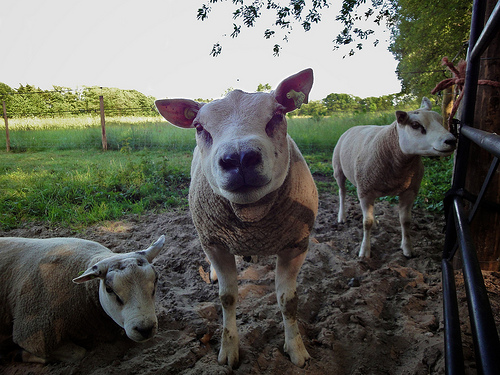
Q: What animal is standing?
A: Sheep.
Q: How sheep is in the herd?
A: 3.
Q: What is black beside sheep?
A: Fence.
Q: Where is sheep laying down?
A: Mud.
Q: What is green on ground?
A: Grass.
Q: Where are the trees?
A: Behind sheep.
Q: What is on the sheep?
A: Ears.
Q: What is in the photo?
A: Sheep.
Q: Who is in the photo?
A: Sheep.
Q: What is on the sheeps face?
A: A nose.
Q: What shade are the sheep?
A: White.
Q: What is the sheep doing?
A: Lying down.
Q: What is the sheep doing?
A: Standing.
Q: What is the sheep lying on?
A: Sand.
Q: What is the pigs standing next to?
A: Black gate.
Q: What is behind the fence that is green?
A: Tall grass.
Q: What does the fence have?
A: Brown posts.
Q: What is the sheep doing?
A: Facing the camera.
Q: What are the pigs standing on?
A: Mud.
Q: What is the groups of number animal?
A: Three.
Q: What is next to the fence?
A: Black iron frence.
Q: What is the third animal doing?
A: Looking at the fence.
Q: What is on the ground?
A: Green grass.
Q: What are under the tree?
A: Gate.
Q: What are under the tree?
A: Sheep.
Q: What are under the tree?
A: Gate.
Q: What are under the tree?
A: Grass.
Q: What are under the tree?
A: Sheeps.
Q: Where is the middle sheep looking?
A: At the camera.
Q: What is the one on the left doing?
A: Laying down.